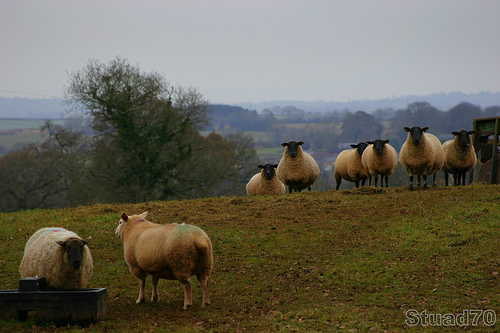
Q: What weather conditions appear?
A: It is cloudy.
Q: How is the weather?
A: It is cloudy.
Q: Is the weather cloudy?
A: Yes, it is cloudy.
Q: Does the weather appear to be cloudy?
A: Yes, it is cloudy.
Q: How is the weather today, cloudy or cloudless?
A: It is cloudy.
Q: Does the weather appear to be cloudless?
A: No, it is cloudy.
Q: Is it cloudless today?
A: No, it is cloudy.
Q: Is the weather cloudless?
A: No, it is cloudy.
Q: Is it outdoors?
A: Yes, it is outdoors.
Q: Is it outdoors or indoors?
A: It is outdoors.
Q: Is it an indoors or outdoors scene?
A: It is outdoors.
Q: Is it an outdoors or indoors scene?
A: It is outdoors.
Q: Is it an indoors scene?
A: No, it is outdoors.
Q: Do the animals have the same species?
A: Yes, all the animals are sheep.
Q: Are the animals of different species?
A: No, all the animals are sheep.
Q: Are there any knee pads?
A: No, there are no knee pads.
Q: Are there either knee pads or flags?
A: No, there are no knee pads or flags.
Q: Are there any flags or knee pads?
A: No, there are no knee pads or flags.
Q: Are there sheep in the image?
A: Yes, there is a sheep.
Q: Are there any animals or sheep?
A: Yes, there is a sheep.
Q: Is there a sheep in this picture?
A: Yes, there is a sheep.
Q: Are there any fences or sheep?
A: Yes, there is a sheep.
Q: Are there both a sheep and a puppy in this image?
A: No, there is a sheep but no puppies.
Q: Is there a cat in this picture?
A: No, there are no cats.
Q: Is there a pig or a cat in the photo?
A: No, there are no cats or pigs.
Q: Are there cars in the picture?
A: No, there are no cars.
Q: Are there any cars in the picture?
A: No, there are no cars.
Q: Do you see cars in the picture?
A: No, there are no cars.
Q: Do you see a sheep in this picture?
A: Yes, there is a sheep.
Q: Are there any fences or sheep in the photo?
A: Yes, there is a sheep.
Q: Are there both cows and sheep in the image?
A: No, there is a sheep but no cows.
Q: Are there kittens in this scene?
A: No, there are no kittens.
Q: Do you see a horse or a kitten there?
A: No, there are no kittens or horses.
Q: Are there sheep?
A: Yes, there is a sheep.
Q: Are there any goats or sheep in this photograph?
A: Yes, there is a sheep.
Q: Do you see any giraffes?
A: No, there are no giraffes.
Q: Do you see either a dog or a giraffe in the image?
A: No, there are no giraffes or dogs.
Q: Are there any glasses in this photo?
A: No, there are no glasses.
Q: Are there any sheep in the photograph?
A: Yes, there is a sheep.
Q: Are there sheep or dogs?
A: Yes, there is a sheep.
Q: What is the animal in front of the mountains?
A: The animal is a sheep.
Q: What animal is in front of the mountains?
A: The animal is a sheep.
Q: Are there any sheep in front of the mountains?
A: Yes, there is a sheep in front of the mountains.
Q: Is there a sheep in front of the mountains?
A: Yes, there is a sheep in front of the mountains.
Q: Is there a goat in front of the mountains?
A: No, there is a sheep in front of the mountains.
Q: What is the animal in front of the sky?
A: The animal is a sheep.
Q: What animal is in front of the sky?
A: The animal is a sheep.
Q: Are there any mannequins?
A: No, there are no mannequins.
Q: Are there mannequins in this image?
A: No, there are no mannequins.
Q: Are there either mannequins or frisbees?
A: No, there are no mannequins or frisbees.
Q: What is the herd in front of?
A: The herd is in front of the mountains.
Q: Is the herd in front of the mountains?
A: Yes, the herd is in front of the mountains.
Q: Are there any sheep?
A: Yes, there is a sheep.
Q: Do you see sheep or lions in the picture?
A: Yes, there is a sheep.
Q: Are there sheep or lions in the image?
A: Yes, there is a sheep.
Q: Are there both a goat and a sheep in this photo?
A: No, there is a sheep but no goats.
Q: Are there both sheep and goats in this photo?
A: No, there is a sheep but no goats.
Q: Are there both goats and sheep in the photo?
A: No, there is a sheep but no goats.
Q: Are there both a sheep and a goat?
A: No, there is a sheep but no goats.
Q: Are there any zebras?
A: No, there are no zebras.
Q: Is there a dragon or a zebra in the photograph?
A: No, there are no zebras or dragons.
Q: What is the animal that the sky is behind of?
A: The animal is a sheep.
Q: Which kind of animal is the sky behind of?
A: The sky is behind the sheep.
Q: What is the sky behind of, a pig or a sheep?
A: The sky is behind a sheep.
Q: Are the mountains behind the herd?
A: Yes, the mountains are behind the herd.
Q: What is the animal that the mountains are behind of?
A: The animal is a sheep.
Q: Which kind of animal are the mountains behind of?
A: The mountains are behind the sheep.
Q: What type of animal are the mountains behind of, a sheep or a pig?
A: The mountains are behind a sheep.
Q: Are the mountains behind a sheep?
A: Yes, the mountains are behind a sheep.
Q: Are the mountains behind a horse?
A: No, the mountains are behind a sheep.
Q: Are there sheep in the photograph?
A: Yes, there is a sheep.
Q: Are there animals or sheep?
A: Yes, there is a sheep.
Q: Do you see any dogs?
A: No, there are no dogs.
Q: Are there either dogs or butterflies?
A: No, there are no dogs or butterflies.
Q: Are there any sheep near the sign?
A: Yes, there is a sheep near the sign.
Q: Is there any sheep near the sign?
A: Yes, there is a sheep near the sign.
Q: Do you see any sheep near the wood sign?
A: Yes, there is a sheep near the sign.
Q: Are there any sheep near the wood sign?
A: Yes, there is a sheep near the sign.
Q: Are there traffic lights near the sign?
A: No, there is a sheep near the sign.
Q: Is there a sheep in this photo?
A: Yes, there is a sheep.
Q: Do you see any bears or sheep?
A: Yes, there is a sheep.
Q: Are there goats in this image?
A: No, there are no goats.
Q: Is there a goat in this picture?
A: No, there are no goats.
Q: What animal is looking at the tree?
A: The sheep is looking at the tree.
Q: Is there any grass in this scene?
A: Yes, there is grass.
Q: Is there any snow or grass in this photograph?
A: Yes, there is grass.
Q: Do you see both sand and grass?
A: No, there is grass but no sand.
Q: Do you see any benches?
A: No, there are no benches.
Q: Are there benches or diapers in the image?
A: No, there are no benches or diapers.